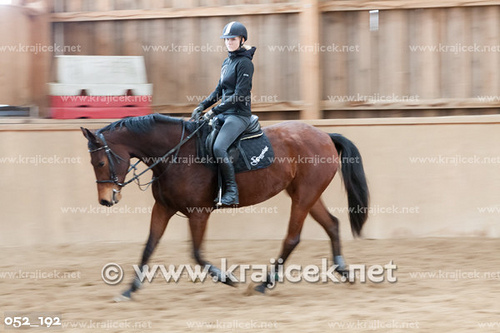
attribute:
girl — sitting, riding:
[188, 19, 255, 212]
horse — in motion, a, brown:
[80, 115, 372, 303]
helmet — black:
[220, 18, 252, 39]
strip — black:
[237, 34, 243, 49]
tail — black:
[327, 131, 373, 242]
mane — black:
[91, 114, 193, 134]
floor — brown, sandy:
[3, 115, 498, 331]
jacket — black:
[201, 46, 256, 115]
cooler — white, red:
[47, 51, 159, 122]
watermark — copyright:
[95, 257, 405, 297]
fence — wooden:
[1, 1, 499, 121]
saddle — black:
[188, 106, 264, 139]